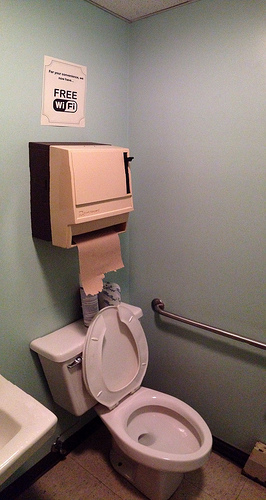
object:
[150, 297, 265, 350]
bar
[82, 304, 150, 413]
seat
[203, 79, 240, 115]
ground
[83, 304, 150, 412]
lid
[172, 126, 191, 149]
ground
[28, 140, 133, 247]
dispenser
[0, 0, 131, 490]
wall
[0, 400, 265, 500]
floor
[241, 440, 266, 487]
box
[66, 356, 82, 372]
handle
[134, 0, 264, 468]
wall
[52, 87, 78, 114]
word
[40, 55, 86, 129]
sign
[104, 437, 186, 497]
base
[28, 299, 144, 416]
water bowl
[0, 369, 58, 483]
bathroom sink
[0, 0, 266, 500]
bathroom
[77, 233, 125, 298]
paper